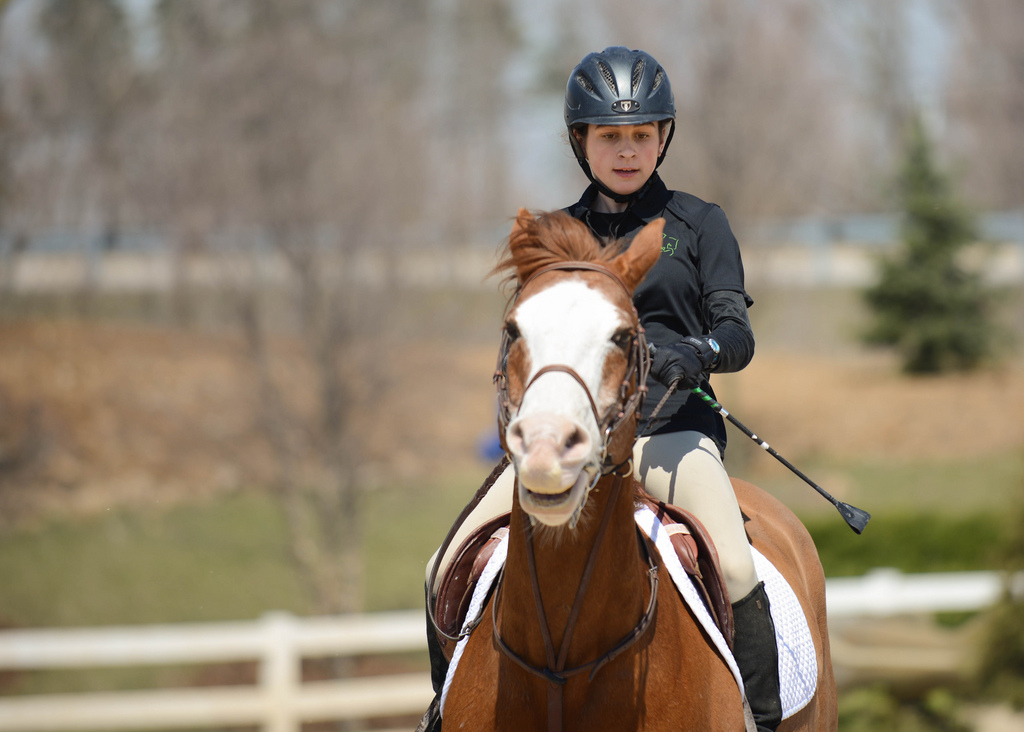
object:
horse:
[421, 206, 837, 731]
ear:
[614, 216, 666, 293]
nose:
[506, 417, 593, 462]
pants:
[424, 429, 764, 604]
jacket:
[528, 169, 756, 463]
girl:
[416, 42, 781, 732]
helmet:
[564, 46, 677, 126]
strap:
[569, 120, 686, 203]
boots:
[731, 580, 785, 732]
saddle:
[435, 501, 736, 669]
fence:
[0, 571, 1019, 732]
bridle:
[488, 264, 661, 691]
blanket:
[438, 529, 819, 720]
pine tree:
[859, 116, 996, 381]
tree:
[132, 0, 441, 732]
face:
[496, 270, 631, 527]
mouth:
[517, 461, 593, 515]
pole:
[692, 386, 872, 535]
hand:
[651, 336, 716, 396]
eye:
[610, 325, 634, 352]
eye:
[504, 320, 520, 347]